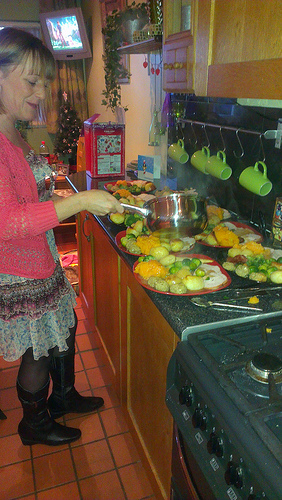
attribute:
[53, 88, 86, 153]
tree — for Christmas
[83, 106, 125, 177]
box — red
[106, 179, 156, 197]
plate — full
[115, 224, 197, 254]
plate — full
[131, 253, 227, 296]
plate — full, food-filled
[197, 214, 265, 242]
plate — full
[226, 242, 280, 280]
plate — full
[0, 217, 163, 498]
floor — brown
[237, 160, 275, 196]
cup — green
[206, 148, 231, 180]
cup — green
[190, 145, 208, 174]
cup — green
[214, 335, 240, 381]
stove top — pictured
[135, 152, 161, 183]
card — Christmas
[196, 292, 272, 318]
spoon — silver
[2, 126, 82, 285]
blouse — pink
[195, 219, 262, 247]
plate — food-filled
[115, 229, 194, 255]
plate — food-filled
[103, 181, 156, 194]
plate — food-filled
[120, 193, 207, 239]
pot — stainless steel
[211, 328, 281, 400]
range — black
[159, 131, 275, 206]
cups — hunging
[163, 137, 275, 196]
cups — green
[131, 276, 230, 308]
plate — red